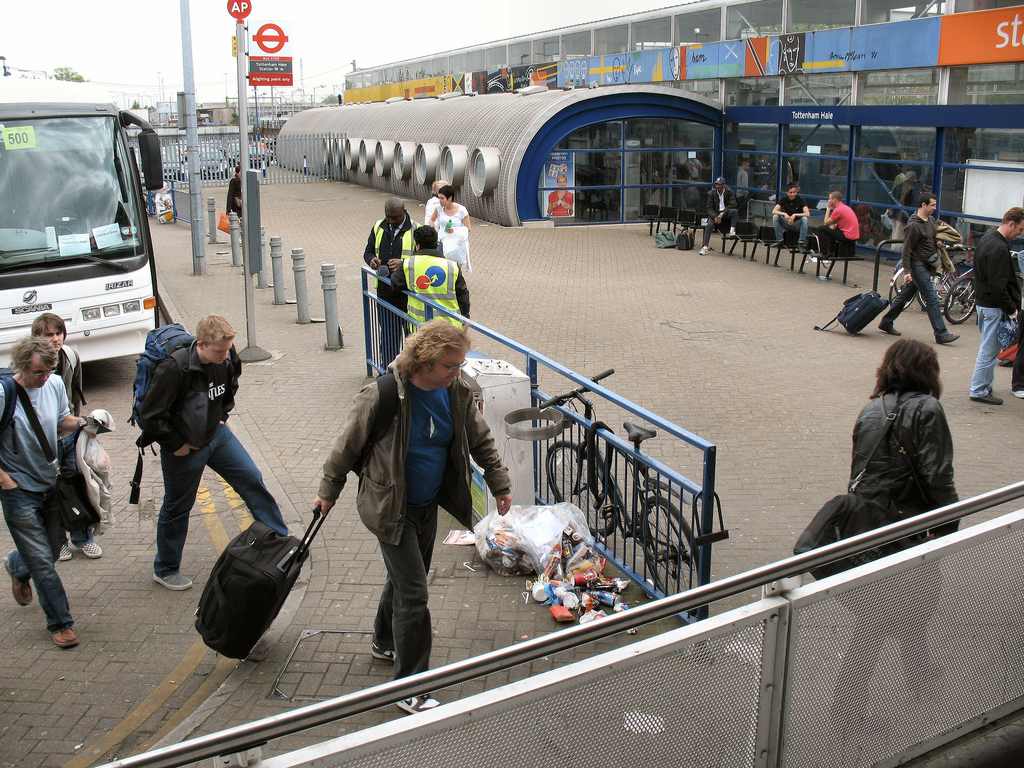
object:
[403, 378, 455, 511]
mans shirt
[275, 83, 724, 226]
building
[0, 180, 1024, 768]
road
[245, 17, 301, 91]
sign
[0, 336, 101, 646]
person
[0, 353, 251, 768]
street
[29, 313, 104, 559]
person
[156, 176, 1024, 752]
sidewalk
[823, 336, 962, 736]
person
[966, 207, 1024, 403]
person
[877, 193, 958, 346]
person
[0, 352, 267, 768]
street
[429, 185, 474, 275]
person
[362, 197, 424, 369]
person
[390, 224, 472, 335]
person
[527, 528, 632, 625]
trash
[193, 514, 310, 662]
suitcase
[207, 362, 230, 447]
shirt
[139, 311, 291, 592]
person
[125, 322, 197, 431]
backpack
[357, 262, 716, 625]
fence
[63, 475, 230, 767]
lines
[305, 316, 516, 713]
man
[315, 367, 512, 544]
jacket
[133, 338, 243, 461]
jacket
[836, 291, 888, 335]
suitcase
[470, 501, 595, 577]
trash bag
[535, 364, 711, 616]
bike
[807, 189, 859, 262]
men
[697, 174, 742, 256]
man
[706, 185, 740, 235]
jacket